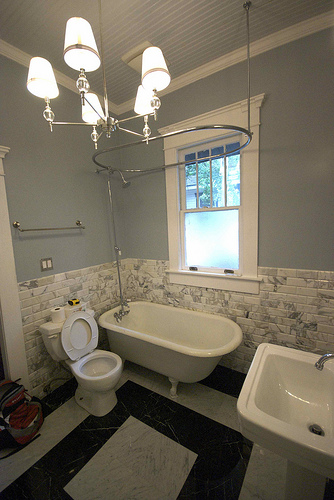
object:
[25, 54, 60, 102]
light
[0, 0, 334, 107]
ceiling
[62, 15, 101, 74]
light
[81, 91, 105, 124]
light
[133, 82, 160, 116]
light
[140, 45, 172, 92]
light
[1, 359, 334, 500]
floor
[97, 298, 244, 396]
bathtub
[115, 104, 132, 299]
corner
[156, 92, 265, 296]
window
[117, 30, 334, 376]
wall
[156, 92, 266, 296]
frame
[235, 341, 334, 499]
sink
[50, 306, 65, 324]
tissue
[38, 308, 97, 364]
tank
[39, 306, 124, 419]
toilet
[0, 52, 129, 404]
wall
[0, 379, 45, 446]
backpack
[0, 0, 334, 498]
bathroom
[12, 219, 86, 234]
towel rack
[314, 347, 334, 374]
faucet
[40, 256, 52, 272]
light switch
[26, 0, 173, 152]
chandelier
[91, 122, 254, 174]
curtain holder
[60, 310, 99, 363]
toilet seat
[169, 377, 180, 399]
claw foot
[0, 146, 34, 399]
door